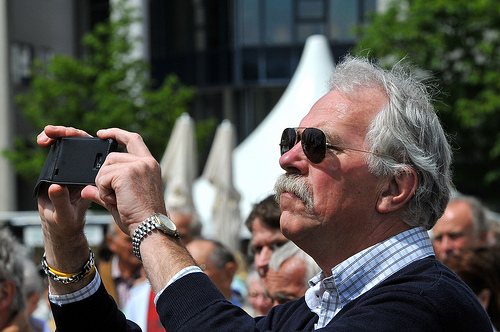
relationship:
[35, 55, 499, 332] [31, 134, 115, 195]
man holding camera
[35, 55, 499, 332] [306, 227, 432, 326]
man wearing a shirt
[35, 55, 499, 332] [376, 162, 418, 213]
man has an ear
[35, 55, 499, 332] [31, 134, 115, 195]
man has a phone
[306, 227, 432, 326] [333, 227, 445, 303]
shirt has a collar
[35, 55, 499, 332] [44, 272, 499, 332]
man has a sweater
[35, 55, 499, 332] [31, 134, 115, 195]
man holding phone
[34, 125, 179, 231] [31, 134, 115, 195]
hands are holding a camera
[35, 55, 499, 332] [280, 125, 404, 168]
man has glasses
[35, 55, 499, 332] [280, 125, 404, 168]
man has sunglasses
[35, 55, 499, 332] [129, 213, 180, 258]
man has a watch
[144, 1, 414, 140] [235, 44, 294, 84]
building has windows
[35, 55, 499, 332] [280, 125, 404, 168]
man wearing sunglasses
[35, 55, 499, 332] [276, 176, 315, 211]
man has a moustache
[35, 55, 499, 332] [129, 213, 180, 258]
man wearing a watch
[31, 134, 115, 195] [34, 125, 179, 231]
phone in hands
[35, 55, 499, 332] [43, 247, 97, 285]
man has a bracelet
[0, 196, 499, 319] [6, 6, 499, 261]
people are in distance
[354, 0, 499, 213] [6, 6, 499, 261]
tree in distance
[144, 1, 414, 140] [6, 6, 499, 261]
building in distance